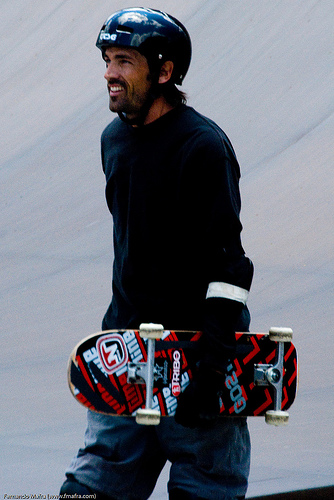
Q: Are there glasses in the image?
A: No, there are no glasses.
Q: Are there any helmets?
A: Yes, there is a helmet.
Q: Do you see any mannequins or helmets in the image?
A: Yes, there is a helmet.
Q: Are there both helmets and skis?
A: No, there is a helmet but no skis.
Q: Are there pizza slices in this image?
A: No, there are no pizza slices.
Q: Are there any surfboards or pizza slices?
A: No, there are no pizza slices or surfboards.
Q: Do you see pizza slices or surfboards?
A: No, there are no pizza slices or surfboards.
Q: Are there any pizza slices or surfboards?
A: No, there are no pizza slices or surfboards.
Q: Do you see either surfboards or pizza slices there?
A: No, there are no pizza slices or surfboards.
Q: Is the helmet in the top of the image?
A: Yes, the helmet is in the top of the image.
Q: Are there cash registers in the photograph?
A: No, there are no cash registers.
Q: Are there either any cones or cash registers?
A: No, there are no cash registers or cones.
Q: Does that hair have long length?
A: Yes, the hair is long.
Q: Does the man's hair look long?
A: Yes, the hair is long.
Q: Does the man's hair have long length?
A: Yes, the hair is long.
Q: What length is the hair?
A: The hair is long.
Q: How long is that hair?
A: The hair is long.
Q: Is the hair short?
A: No, the hair is long.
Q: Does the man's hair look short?
A: No, the hair is long.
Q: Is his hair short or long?
A: The hair is long.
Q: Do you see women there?
A: No, there are no women.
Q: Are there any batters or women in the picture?
A: No, there are no women or batters.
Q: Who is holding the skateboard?
A: The man is holding the skateboard.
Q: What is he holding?
A: The man is holding the skateboard.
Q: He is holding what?
A: The man is holding the skateboard.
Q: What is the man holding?
A: The man is holding the skateboard.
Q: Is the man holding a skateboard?
A: Yes, the man is holding a skateboard.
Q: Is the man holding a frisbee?
A: No, the man is holding a skateboard.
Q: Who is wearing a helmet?
A: The man is wearing a helmet.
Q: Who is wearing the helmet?
A: The man is wearing a helmet.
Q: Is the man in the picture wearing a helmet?
A: Yes, the man is wearing a helmet.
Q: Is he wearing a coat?
A: No, the man is wearing a helmet.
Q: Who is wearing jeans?
A: The man is wearing jeans.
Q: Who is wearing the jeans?
A: The man is wearing jeans.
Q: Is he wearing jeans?
A: Yes, the man is wearing jeans.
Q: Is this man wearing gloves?
A: No, the man is wearing jeans.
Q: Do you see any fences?
A: No, there are no fences.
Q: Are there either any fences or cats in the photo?
A: No, there are no fences or cats.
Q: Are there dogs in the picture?
A: No, there are no dogs.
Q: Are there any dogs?
A: No, there are no dogs.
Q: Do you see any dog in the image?
A: No, there are no dogs.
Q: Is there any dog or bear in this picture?
A: No, there are no dogs or bears.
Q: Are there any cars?
A: No, there are no cars.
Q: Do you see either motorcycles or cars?
A: No, there are no cars or motorcycles.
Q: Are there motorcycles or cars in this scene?
A: No, there are no cars or motorcycles.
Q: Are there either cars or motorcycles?
A: No, there are no cars or motorcycles.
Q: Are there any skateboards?
A: Yes, there is a skateboard.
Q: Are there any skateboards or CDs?
A: Yes, there is a skateboard.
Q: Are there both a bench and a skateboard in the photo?
A: No, there is a skateboard but no benches.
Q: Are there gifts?
A: No, there are no gifts.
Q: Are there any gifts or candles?
A: No, there are no gifts or candles.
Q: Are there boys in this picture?
A: No, there are no boys.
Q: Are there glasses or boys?
A: No, there are no boys or glasses.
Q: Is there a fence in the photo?
A: No, there are no fences.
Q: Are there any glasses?
A: No, there are no glasses.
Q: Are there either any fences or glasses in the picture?
A: No, there are no glasses or fences.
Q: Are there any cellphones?
A: No, there are no cellphones.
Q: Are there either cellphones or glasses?
A: No, there are no cellphones or glasses.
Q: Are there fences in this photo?
A: No, there are no fences.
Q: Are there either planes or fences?
A: No, there are no fences or planes.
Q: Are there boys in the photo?
A: No, there are no boys.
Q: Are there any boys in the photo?
A: No, there are no boys.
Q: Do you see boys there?
A: No, there are no boys.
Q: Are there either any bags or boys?
A: No, there are no boys or bags.